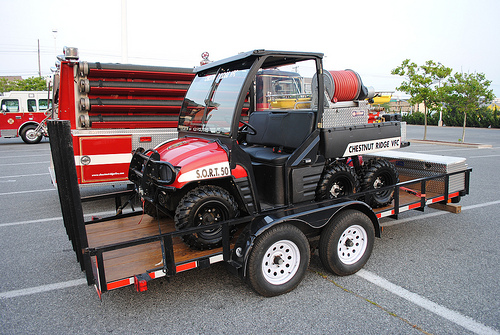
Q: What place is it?
A: It is a road.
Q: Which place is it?
A: It is a road.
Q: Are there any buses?
A: Yes, there is a bus.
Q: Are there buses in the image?
A: Yes, there is a bus.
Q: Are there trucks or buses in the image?
A: Yes, there is a bus.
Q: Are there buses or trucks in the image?
A: Yes, there is a bus.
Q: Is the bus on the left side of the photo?
A: Yes, the bus is on the left of the image.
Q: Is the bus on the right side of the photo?
A: No, the bus is on the left of the image.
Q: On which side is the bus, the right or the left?
A: The bus is on the left of the image.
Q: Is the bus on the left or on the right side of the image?
A: The bus is on the left of the image.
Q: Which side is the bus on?
A: The bus is on the left of the image.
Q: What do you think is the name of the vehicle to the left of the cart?
A: The vehicle is a bus.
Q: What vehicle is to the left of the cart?
A: The vehicle is a bus.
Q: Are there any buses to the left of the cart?
A: Yes, there is a bus to the left of the cart.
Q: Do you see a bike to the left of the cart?
A: No, there is a bus to the left of the cart.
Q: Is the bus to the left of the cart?
A: Yes, the bus is to the left of the cart.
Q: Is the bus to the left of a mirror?
A: No, the bus is to the left of the cart.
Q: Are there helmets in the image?
A: No, there are no helmets.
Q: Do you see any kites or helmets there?
A: No, there are no helmets or kites.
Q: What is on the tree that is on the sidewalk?
A: The leaves are on the tree.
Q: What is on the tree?
A: The leaves are on the tree.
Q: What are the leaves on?
A: The leaves are on the tree.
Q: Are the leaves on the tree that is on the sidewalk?
A: Yes, the leaves are on the tree.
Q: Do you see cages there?
A: No, there are no cages.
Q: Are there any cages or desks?
A: No, there are no cages or desks.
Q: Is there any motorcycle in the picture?
A: No, there are no motorcycles.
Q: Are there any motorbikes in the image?
A: No, there are no motorbikes.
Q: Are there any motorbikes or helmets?
A: No, there are no motorbikes or helmets.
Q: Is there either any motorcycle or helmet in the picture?
A: No, there are no motorcycles or helmets.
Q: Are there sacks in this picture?
A: No, there are no sacks.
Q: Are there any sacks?
A: No, there are no sacks.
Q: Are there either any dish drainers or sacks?
A: No, there are no sacks or dish drainers.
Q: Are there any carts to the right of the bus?
A: Yes, there is a cart to the right of the bus.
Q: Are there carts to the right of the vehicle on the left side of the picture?
A: Yes, there is a cart to the right of the bus.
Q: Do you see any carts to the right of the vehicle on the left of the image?
A: Yes, there is a cart to the right of the bus.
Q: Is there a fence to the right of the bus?
A: No, there is a cart to the right of the bus.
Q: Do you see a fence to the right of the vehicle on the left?
A: No, there is a cart to the right of the bus.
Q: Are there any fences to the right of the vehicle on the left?
A: No, there is a cart to the right of the bus.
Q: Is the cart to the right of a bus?
A: Yes, the cart is to the right of a bus.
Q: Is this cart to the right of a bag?
A: No, the cart is to the right of a bus.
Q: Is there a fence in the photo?
A: No, there are no fences.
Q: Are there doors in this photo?
A: Yes, there is a door.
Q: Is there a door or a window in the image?
A: Yes, there is a door.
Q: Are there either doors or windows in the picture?
A: Yes, there is a door.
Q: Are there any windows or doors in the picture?
A: Yes, there is a door.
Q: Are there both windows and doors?
A: Yes, there are both a door and a window.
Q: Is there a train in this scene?
A: No, there are no trains.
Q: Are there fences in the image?
A: No, there are no fences.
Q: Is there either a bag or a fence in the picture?
A: No, there are no fences or bags.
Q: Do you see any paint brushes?
A: No, there are no paint brushes.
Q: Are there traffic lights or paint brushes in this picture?
A: No, there are no paint brushes or traffic lights.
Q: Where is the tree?
A: The tree is on the sidewalk.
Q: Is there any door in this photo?
A: Yes, there is a door.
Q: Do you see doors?
A: Yes, there is a door.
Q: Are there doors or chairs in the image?
A: Yes, there is a door.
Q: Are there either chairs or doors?
A: Yes, there is a door.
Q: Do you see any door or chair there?
A: Yes, there is a door.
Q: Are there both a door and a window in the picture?
A: Yes, there are both a door and a window.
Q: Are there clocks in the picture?
A: No, there are no clocks.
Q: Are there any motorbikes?
A: No, there are no motorbikes.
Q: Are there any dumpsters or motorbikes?
A: No, there are no motorbikes or dumpsters.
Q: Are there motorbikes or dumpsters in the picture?
A: No, there are no motorbikes or dumpsters.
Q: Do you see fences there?
A: No, there are no fences.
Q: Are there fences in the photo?
A: No, there are no fences.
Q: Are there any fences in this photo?
A: No, there are no fences.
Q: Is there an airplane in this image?
A: No, there are no airplanes.